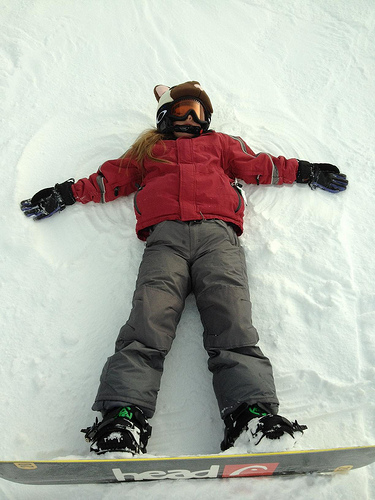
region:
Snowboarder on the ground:
[17, 76, 350, 453]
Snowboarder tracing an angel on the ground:
[20, 76, 346, 455]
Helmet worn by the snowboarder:
[148, 77, 213, 137]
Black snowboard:
[1, 448, 373, 484]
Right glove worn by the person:
[17, 180, 78, 227]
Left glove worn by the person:
[298, 155, 349, 194]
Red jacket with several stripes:
[70, 129, 301, 239]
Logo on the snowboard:
[112, 461, 279, 483]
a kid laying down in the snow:
[12, 68, 314, 447]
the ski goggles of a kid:
[161, 91, 201, 118]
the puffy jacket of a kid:
[84, 120, 317, 232]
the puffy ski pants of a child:
[102, 219, 260, 409]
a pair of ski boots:
[85, 400, 321, 453]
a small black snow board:
[37, 443, 373, 480]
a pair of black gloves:
[18, 178, 70, 216]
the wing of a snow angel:
[36, 95, 122, 181]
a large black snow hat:
[159, 78, 198, 98]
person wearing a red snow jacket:
[96, 124, 269, 220]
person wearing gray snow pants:
[128, 205, 282, 413]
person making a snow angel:
[30, 89, 346, 257]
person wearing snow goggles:
[144, 92, 215, 123]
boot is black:
[218, 396, 309, 454]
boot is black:
[81, 407, 162, 457]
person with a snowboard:
[21, 444, 368, 486]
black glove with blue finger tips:
[286, 151, 352, 199]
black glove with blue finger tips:
[21, 171, 71, 221]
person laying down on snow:
[18, 88, 359, 498]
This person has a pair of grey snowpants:
[232, 385, 239, 400]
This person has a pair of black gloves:
[318, 150, 333, 233]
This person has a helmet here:
[169, 77, 204, 136]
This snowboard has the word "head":
[119, 470, 170, 491]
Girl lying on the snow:
[21, 81, 348, 457]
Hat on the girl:
[152, 80, 213, 116]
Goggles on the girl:
[166, 97, 212, 124]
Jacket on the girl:
[70, 129, 298, 242]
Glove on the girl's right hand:
[19, 177, 75, 222]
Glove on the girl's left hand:
[294, 156, 349, 193]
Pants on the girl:
[90, 219, 280, 416]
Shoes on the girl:
[80, 402, 309, 455]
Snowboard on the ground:
[1, 444, 374, 486]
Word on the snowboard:
[111, 464, 219, 480]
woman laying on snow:
[17, 65, 352, 443]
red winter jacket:
[74, 121, 303, 220]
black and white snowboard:
[1, 447, 366, 483]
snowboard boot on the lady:
[216, 397, 303, 455]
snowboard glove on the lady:
[24, 179, 80, 215]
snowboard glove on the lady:
[295, 157, 344, 191]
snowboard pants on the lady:
[83, 222, 283, 410]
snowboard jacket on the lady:
[69, 123, 300, 228]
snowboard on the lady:
[0, 443, 373, 483]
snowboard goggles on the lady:
[166, 93, 211, 124]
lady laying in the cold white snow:
[10, 83, 353, 467]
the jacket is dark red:
[72, 130, 300, 236]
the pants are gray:
[91, 216, 278, 413]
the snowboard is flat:
[0, 444, 373, 484]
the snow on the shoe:
[218, 405, 308, 456]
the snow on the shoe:
[82, 403, 152, 460]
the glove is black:
[22, 177, 77, 219]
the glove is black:
[296, 158, 348, 194]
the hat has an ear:
[154, 81, 214, 118]